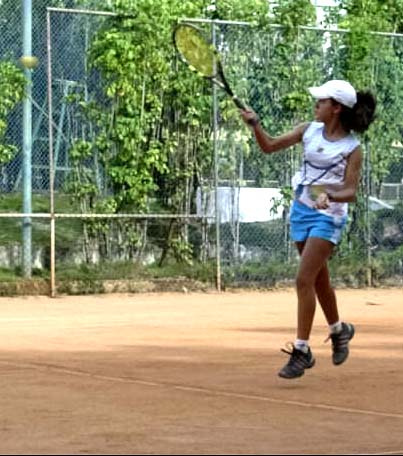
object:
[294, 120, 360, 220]
shirt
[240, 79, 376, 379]
person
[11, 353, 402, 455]
ground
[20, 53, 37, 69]
ball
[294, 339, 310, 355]
sock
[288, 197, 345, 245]
shorts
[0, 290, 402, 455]
court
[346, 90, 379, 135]
hair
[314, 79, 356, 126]
head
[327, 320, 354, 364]
shoe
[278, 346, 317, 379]
shoe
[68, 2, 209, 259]
plant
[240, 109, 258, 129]
hand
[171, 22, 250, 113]
racket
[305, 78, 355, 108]
cap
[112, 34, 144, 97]
leaves